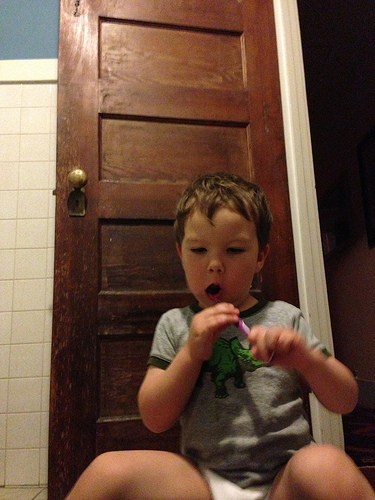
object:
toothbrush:
[208, 288, 257, 340]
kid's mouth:
[204, 278, 224, 302]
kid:
[64, 171, 375, 500]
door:
[46, 0, 311, 498]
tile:
[10, 310, 43, 345]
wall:
[0, 0, 60, 499]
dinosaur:
[200, 335, 269, 399]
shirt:
[144, 295, 332, 487]